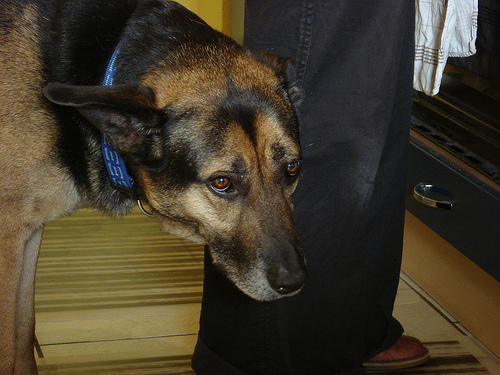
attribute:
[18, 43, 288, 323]
dog — brown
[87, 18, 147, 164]
collar — blue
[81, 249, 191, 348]
carpet — striped, beige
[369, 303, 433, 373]
shoe — brown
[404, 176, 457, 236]
drawer handle — silver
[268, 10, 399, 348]
jeans — blue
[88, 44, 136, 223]
collar — blue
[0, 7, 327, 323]
dog — brown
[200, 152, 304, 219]
eyes — brown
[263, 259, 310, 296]
nose — black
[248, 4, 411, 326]
pants — black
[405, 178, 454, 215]
handle — silver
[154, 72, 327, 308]
face — brown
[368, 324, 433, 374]
shoe — brown